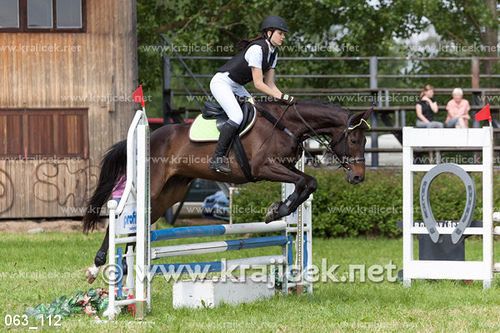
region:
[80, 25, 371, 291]
the horse jumping over the poles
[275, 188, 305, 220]
the brace on the legs of the horse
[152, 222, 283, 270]
the pole on the bars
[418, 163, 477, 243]
the horseshoe on the white fence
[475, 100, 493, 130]
the red flag on the whtie fence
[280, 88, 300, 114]
the reigns in the hands of the women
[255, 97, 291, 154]
the whip by the side of the horse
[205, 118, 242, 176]
the boot in the stir-up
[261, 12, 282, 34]
the black helmet on the head of the women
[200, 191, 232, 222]
the front of the cars int he parking lot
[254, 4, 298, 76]
a woman wearing a black helmet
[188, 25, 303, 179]
a woman wearing black boots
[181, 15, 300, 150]
a woman wearing white pants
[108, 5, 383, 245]
a woman riding a horse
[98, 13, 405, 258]
a woman riding a brown horse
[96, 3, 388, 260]
a woman jumping a horse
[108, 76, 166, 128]
a red flag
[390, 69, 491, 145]
two people sitting down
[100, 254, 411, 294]
web address on bottom of picture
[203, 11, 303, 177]
person wearing black and white riding horse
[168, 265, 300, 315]
white box below jump in grass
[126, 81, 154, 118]
red flag attached to white pole next to horse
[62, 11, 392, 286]
brown horse jumping with rider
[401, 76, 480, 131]
two woman sitting in stands in back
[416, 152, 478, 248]
silver horse shoe symbol on fence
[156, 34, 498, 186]
gray bleachers in back of picture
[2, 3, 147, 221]
brown building in left of picture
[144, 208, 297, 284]
blue and white poles used for jump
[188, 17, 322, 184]
this is a woman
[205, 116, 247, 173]
this is a riding boot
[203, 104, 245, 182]
the riding boot is black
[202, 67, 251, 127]
woman wearing white pants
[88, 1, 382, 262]
woman is riding a horse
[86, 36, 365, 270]
the horse is dark brown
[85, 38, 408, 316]
the horse is jumping a hurdle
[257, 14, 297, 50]
the woman is wearing a black helmet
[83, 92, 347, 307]
a white and blue hurdle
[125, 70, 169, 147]
red flag on top of hurdle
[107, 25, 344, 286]
a horse jumping over a fence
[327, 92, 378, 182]
the head of a brown horse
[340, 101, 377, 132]
the ears of a brown horse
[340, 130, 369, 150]
the eyes of a brown horse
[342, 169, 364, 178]
the nose of a brown horse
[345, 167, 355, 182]
the mouth of a brown horse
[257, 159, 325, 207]
the front legs of a brown horse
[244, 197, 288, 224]
the hooves of a brown horse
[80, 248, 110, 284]
the back hooves of a brown horse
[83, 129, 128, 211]
the tail of a brown horse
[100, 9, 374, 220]
horse and rider jumping obstacle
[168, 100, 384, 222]
brown horse jumping over obstacle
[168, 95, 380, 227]
brown horse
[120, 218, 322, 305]
blue and white obstacle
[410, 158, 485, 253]
silver horseshoe sign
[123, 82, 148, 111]
small red flag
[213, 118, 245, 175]
female rider wearing black boot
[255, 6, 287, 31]
black hat worn by woman rider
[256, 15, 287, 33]
A helmet on a horse rider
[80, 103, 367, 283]
A horse jumping a pole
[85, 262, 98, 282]
A hoof on a horse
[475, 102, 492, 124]
A red flag on an obstacle